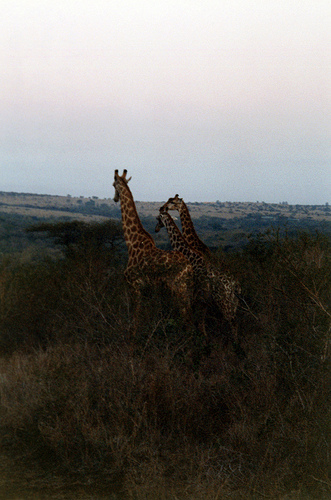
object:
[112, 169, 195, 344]
giraffe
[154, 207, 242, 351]
giraffe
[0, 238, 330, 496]
grass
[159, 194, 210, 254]
giraffe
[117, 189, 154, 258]
neck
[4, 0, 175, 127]
sky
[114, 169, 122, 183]
horn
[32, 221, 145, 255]
tree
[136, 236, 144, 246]
spot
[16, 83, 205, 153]
cloud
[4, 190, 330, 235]
field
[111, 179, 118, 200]
face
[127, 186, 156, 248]
hair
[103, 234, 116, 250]
branch